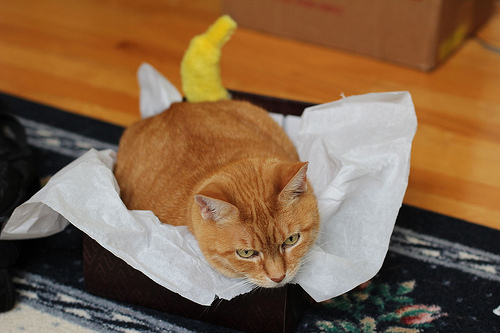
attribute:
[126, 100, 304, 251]
cat — brown, laying, sitting, orange, fat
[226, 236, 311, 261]
eyes — green, bright, open, olive colored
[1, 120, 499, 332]
rug — blue, white, dark blue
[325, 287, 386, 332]
flowers — pink, design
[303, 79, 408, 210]
paper — white, tissue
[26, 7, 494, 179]
floor — wood, wooden, polished, hardwood, light colored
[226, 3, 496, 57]
box — cardboard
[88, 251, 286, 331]
box — small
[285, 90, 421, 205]
tissue — white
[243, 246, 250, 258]
dot — black, center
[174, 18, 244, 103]
toy — yellow, stuffed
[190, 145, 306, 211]
ears — small, pointy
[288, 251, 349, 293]
whiskers — thin, white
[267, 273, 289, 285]
nose — pink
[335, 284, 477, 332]
pattern — floral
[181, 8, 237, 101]
banana — plush, yellow